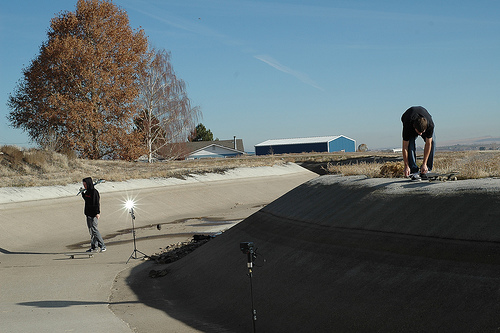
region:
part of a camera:
[246, 296, 259, 298]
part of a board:
[423, 171, 428, 176]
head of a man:
[418, 123, 424, 132]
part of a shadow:
[66, 300, 72, 309]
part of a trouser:
[96, 227, 104, 236]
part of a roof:
[301, 134, 308, 140]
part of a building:
[303, 134, 310, 148]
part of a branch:
[136, 122, 151, 139]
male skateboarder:
[385, 95, 436, 175]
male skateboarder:
[65, 175, 110, 243]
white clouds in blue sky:
[176, 15, 246, 65]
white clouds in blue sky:
[186, 48, 241, 83]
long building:
[243, 125, 354, 160]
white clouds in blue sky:
[265, 20, 315, 86]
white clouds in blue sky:
[261, 61, 301, 86]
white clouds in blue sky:
[277, 68, 328, 99]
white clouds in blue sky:
[331, 35, 381, 80]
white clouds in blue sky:
[420, 12, 465, 47]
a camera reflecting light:
[120, 195, 145, 246]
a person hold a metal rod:
[57, 168, 113, 250]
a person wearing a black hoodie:
[74, 172, 113, 249]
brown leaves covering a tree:
[21, 3, 146, 154]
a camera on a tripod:
[234, 237, 267, 331]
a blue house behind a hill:
[162, 134, 251, 164]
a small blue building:
[254, 132, 354, 154]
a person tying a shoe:
[391, 101, 447, 178]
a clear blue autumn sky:
[174, 2, 462, 90]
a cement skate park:
[6, 177, 488, 309]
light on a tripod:
[114, 186, 151, 264]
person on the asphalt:
[73, 171, 118, 268]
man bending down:
[383, 102, 460, 192]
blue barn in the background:
[247, 123, 372, 169]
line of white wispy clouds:
[197, 28, 320, 116]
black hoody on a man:
[80, 168, 105, 220]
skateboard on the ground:
[62, 236, 97, 268]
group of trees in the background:
[15, 2, 217, 181]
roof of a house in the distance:
[150, 121, 249, 163]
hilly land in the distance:
[448, 136, 498, 169]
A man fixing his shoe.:
[390, 95, 440, 182]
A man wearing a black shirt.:
[390, 98, 438, 178]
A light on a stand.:
[234, 228, 271, 327]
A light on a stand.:
[117, 192, 154, 277]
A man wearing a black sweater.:
[73, 175, 111, 262]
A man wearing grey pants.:
[77, 170, 109, 261]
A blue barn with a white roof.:
[253, 130, 359, 156]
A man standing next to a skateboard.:
[396, 97, 463, 190]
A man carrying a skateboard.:
[65, 170, 116, 252]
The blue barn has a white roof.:
[249, 135, 358, 158]